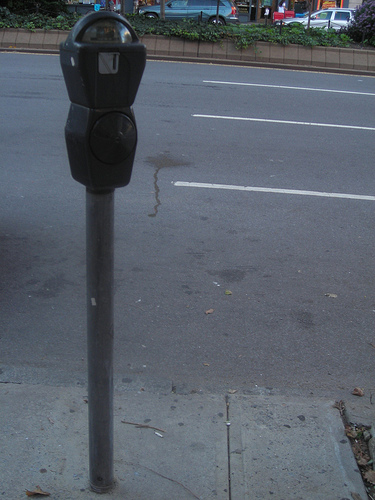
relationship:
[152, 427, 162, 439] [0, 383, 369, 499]
cigarette on sidewalk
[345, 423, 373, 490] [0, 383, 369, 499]
leaves near sidewalk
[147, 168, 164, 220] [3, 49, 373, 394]
crack in road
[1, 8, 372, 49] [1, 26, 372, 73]
bushes in planter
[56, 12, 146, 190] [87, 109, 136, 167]
parking meter has lid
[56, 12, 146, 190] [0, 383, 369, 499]
parking meter on sidewalk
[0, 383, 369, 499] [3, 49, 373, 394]
sidewalk next to road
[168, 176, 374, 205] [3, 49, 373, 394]
line on road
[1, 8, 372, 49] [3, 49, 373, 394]
bushes by road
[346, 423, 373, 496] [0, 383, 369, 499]
dirt next to sidewalk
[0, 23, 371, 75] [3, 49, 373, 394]
median by road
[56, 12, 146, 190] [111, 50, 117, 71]
parking meter has coin slot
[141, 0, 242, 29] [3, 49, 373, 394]
cars b road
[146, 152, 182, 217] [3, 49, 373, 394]
spill i road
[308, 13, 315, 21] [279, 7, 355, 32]
mirror of car